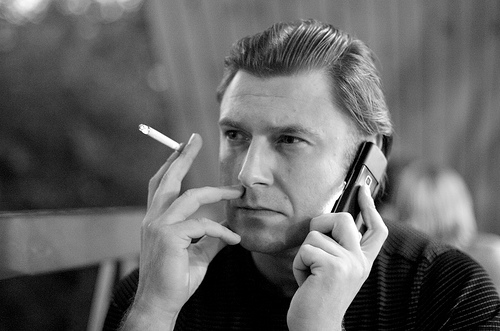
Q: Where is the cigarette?
A: In the man's right hand.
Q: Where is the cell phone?
A: In the man's left hand.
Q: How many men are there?
A: One.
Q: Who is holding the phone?
A: The man.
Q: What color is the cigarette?
A: White.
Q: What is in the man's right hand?
A: The cigarette.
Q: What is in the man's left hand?
A: The cell phone.